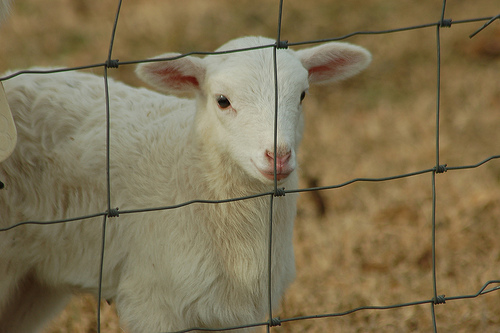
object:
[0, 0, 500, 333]
fence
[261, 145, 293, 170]
nose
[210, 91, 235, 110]
eye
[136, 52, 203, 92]
ear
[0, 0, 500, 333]
grass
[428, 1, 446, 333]
wire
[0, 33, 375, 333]
sheep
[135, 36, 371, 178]
head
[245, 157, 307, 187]
mouth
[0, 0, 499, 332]
field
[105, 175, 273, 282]
fur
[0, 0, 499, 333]
ground